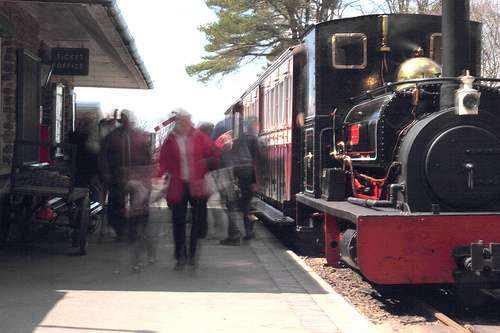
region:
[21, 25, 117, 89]
sign for ticket office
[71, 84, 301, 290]
people are out of focus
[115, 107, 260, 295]
lady in red is pointing at train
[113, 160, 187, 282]
child is holding hands with lady in red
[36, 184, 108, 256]
bench against wall of ticket office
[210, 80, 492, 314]
old-fashioned train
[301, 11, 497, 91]
front windows the train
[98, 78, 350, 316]
loading dock for train station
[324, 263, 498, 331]
train tracks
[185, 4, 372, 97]
tall tree in background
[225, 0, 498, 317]
train is red and black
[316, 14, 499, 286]
train is locomotive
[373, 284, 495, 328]
train is on tracks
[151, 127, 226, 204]
person wearing red coat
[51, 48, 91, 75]
sign says ticket office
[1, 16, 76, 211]
wall of buliding is brick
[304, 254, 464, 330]
gravel next to train tracks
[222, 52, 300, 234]
train carries passengers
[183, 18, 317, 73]
tree leaves are green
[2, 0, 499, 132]
The sky is bright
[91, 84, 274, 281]
people walking next to the train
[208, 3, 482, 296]
red and black train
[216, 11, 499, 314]
train sitting on the tracks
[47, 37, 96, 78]
sign indicating it's the ticket office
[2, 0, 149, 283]
ticket office building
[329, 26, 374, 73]
black square outlined in silver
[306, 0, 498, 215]
black steam engine on the front of the train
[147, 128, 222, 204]
red hacket that is hanging open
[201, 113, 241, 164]
hand pointing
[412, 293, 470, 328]
rod of the railroad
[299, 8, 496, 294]
a black vintage train engine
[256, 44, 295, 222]
a train passenger car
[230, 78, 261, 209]
a train passenger car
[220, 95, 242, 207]
a train passenger car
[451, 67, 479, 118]
a train front lantern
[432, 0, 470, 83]
a black train smoke stack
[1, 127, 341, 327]
a train boarding platform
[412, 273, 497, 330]
a set of train tracks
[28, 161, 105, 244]
an outside park bench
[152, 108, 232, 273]
a blurred pedestrian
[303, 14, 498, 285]
the engine of a train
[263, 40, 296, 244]
a car of the train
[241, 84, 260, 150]
a car of the train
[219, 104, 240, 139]
a car of the train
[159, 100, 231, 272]
an out of focus person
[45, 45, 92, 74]
a sign for the ticket office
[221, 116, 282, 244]
a person out of focus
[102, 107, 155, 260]
a person out of focus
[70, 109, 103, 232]
a person out of focus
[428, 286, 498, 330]
train tracks